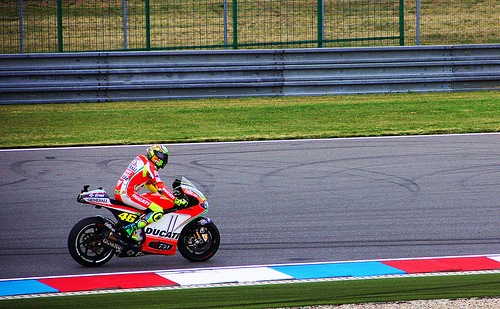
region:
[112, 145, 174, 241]
Man riding a motorcycle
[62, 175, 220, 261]
Red, white and black motorcycle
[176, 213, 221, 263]
Front wheel of the motorcycle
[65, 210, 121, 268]
Rear wheel of the motorcycle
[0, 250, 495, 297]
Blue, red and white patches on side of raceway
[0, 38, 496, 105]
Dark blue/gray guardrail next to fence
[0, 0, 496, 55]
Wire fence in back of guard rail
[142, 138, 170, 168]
Multi-colored helmet worn by motor cyclist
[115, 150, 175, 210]
red and white outfit man is wearing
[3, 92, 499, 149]
Grass on the side of the raceway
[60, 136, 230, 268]
a motorcycle runs on a racetrack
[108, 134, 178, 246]
motorcyclist wears red suit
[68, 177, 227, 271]
motorcycle is red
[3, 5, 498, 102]
fence on side a racetrack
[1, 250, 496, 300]
a striped line on side a racetrack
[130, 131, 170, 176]
motorcyclist wears a green and red helmet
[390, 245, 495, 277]
red part of a stripe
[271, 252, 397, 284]
blue part of a stripe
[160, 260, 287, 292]
white part of a stripe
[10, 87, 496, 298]
green grass on side the racetrack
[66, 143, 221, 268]
Driver racing motorbike on track.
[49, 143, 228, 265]
a motorcycle racer on a track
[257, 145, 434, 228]
burnout tire marks on asphalt track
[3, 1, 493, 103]
metal fence separating a track from the outside field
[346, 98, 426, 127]
grass between a race track and fence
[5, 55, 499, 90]
metal retaining wall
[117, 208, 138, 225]
bright yellow number on a motorcycle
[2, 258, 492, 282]
buffer between the racetrack and grass infield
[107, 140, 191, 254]
motorcycle racer outfitted in special clothing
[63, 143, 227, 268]
motorcycle racer heading down a straightaway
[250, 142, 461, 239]
asphalt pavement of a racetrack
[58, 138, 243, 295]
a racer riding the bike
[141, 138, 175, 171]
the racer is wearing a helmet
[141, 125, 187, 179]
the racer is wearing a helmet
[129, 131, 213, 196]
the racer is wearing a helmet